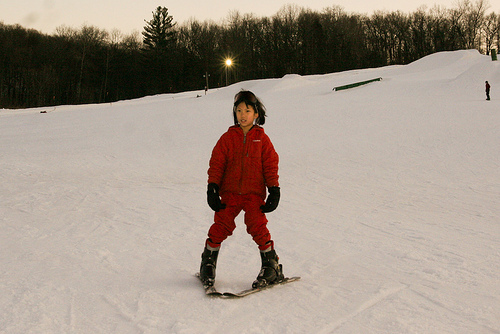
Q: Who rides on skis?
A: A skier.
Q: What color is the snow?
A: White.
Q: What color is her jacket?
A: Red.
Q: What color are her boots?
A: Black.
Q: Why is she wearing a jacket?
A: For warmth.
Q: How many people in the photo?
A: Two.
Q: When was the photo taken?
A: Dusk.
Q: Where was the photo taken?
A: Outdoors.